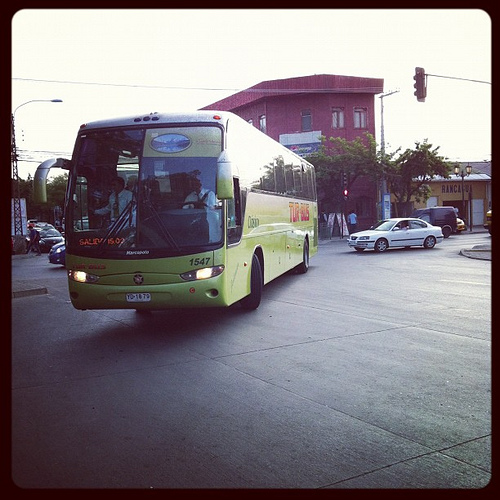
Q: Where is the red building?
A: Behind the bus.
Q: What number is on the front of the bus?
A: 1547.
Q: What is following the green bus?
A: A white sedan.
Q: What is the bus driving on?
A: A street.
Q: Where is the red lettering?
A: On the side of the bus.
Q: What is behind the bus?
A: A brick building.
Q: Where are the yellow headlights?
A: On the front of the bus.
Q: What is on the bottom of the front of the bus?
A: A license plate.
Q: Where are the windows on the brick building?
A: Near the top of the building.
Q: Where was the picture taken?
A: In a city.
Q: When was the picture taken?
A: Daytime.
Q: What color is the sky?
A: White.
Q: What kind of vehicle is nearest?
A: A bus.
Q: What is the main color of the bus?
A: Green.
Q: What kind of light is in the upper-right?
A: A traffic light.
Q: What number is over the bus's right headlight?
A: 1547.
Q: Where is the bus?
A: In the road.